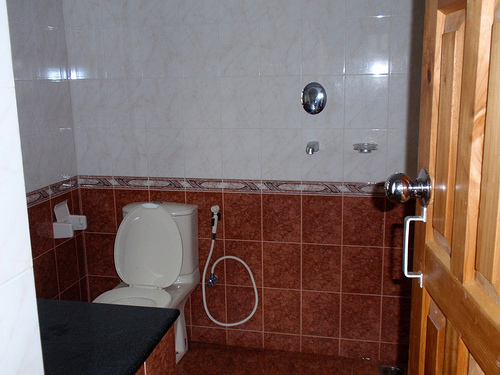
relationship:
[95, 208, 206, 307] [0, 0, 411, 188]
toilet near wall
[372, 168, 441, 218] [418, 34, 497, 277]
knob on door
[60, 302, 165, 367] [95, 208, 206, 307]
counter near toilet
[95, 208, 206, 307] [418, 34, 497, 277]
toilet near door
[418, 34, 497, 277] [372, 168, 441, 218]
door has knob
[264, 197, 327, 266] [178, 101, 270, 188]
tiles on a wall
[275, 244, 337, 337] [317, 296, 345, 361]
red textured tile